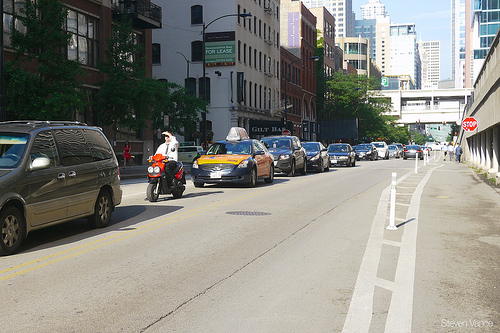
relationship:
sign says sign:
[459, 115, 481, 135] [459, 115, 481, 135]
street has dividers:
[1, 136, 416, 260] [388, 144, 428, 237]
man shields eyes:
[155, 130, 180, 171] [165, 130, 169, 139]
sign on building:
[459, 115, 481, 135] [444, 39, 500, 181]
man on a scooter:
[155, 130, 180, 171] [145, 151, 186, 196]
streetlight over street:
[194, 10, 255, 140] [1, 136, 416, 260]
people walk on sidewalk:
[438, 139, 465, 161] [393, 156, 500, 332]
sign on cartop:
[226, 123, 255, 140] [207, 136, 266, 155]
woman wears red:
[123, 140, 135, 168] [126, 149, 130, 158]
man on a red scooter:
[155, 130, 180, 171] [145, 151, 186, 196]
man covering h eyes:
[155, 130, 180, 171] [165, 130, 169, 139]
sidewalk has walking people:
[393, 156, 500, 332] [438, 139, 465, 161]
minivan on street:
[2, 116, 123, 253] [1, 136, 416, 260]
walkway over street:
[370, 86, 467, 126] [1, 136, 416, 260]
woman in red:
[123, 140, 135, 168] [126, 149, 130, 158]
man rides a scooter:
[155, 130, 180, 171] [145, 151, 186, 196]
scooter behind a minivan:
[145, 151, 186, 196] [2, 116, 123, 253]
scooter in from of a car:
[145, 151, 186, 196] [189, 135, 278, 187]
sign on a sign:
[459, 115, 481, 135] [459, 115, 481, 135]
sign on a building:
[202, 39, 240, 68] [166, 1, 279, 134]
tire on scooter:
[149, 178, 166, 203] [145, 151, 186, 196]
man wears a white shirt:
[155, 130, 180, 171] [155, 133, 180, 160]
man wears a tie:
[155, 130, 180, 171] [166, 144, 169, 157]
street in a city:
[1, 136, 416, 260] [1, 2, 500, 332]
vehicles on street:
[1, 118, 429, 205] [1, 136, 416, 260]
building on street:
[444, 39, 500, 181] [1, 136, 416, 260]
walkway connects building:
[370, 86, 467, 126] [444, 39, 500, 181]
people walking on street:
[438, 139, 465, 161] [1, 136, 416, 260]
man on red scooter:
[155, 130, 180, 171] [145, 151, 186, 196]